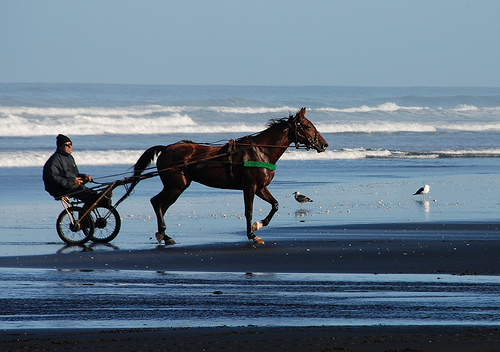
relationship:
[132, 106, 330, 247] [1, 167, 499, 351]
horse on beach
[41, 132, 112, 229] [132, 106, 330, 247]
man being pulled by horse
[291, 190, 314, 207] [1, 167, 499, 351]
bird on beach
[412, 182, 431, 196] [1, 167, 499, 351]
bird on beach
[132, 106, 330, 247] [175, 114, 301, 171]
horse has harness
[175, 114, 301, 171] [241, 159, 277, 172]
harness has strap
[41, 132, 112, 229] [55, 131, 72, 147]
man wearing stocking cap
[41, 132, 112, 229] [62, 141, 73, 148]
man wearing sunglasses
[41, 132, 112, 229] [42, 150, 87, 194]
man wearing windbreaker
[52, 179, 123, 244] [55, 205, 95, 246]
carriage has wheel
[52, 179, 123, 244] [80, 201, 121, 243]
carriage has wheel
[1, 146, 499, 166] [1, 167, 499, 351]
waves rolling into beach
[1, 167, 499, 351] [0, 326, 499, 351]
beach has part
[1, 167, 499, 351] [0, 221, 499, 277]
beach has part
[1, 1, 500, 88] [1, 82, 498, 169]
sky above ocean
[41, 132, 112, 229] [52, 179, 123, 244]
man sitting on carriage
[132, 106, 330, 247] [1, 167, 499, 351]
horse walking on beach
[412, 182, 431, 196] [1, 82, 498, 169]
bird facing away from ocean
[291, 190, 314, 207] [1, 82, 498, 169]
bird facing toward ocean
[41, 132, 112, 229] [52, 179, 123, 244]
man in carriage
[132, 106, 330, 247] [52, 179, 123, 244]
horse pulling carriage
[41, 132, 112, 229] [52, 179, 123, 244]
man sitting in carriage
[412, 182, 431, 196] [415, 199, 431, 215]
bird has reflection